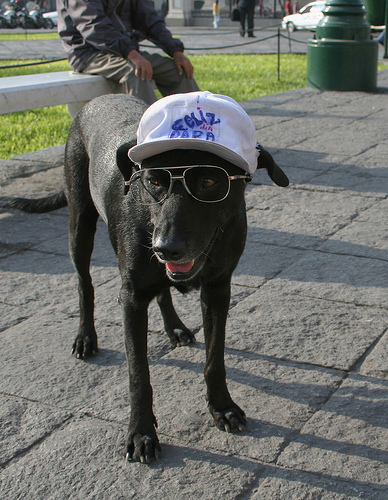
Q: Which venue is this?
A: This is a sidewalk.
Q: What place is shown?
A: It is a sidewalk.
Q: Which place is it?
A: It is a sidewalk.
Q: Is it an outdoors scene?
A: Yes, it is outdoors.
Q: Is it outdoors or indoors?
A: It is outdoors.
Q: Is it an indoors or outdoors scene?
A: It is outdoors.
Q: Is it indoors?
A: No, it is outdoors.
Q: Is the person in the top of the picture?
A: Yes, the person is in the top of the image.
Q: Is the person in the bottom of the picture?
A: No, the person is in the top of the image.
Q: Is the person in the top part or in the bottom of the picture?
A: The person is in the top of the image.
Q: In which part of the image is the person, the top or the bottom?
A: The person is in the top of the image.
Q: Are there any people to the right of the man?
A: Yes, there is a person to the right of the man.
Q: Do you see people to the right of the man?
A: Yes, there is a person to the right of the man.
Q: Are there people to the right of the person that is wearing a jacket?
A: Yes, there is a person to the right of the man.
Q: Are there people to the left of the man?
A: No, the person is to the right of the man.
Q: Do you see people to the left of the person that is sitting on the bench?
A: No, the person is to the right of the man.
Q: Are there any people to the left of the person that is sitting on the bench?
A: No, the person is to the right of the man.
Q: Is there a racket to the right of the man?
A: No, there is a person to the right of the man.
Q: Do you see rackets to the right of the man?
A: No, there is a person to the right of the man.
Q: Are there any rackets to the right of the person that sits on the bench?
A: No, there is a person to the right of the man.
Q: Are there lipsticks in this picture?
A: No, there are no lipsticks.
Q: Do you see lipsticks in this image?
A: No, there are no lipsticks.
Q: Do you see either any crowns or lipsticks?
A: No, there are no lipsticks or crowns.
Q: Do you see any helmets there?
A: No, there are no helmets.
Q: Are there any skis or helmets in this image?
A: No, there are no helmets or skis.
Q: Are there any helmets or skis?
A: No, there are no helmets or skis.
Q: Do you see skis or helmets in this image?
A: No, there are no helmets or skis.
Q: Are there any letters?
A: Yes, there are letters.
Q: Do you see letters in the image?
A: Yes, there are letters.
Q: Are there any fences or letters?
A: Yes, there are letters.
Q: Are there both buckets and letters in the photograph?
A: No, there are letters but no buckets.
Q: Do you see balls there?
A: No, there are no balls.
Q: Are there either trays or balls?
A: No, there are no balls or trays.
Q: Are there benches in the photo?
A: Yes, there is a bench.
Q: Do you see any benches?
A: Yes, there is a bench.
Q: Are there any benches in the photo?
A: Yes, there is a bench.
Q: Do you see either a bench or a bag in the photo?
A: Yes, there is a bench.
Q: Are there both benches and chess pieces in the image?
A: No, there is a bench but no chess pieces.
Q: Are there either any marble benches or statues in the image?
A: Yes, there is a marble bench.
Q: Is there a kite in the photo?
A: No, there are no kites.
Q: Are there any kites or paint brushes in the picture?
A: No, there are no kites or paint brushes.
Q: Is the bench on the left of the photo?
A: Yes, the bench is on the left of the image.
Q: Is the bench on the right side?
A: No, the bench is on the left of the image.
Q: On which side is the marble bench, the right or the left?
A: The bench is on the left of the image.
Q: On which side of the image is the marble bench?
A: The bench is on the left of the image.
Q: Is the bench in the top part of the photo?
A: Yes, the bench is in the top of the image.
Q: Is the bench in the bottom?
A: No, the bench is in the top of the image.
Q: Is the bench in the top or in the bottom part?
A: The bench is in the top of the image.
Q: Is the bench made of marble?
A: Yes, the bench is made of marble.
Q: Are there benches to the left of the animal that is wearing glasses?
A: Yes, there is a bench to the left of the dog.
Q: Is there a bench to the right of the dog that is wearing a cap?
A: No, the bench is to the left of the dog.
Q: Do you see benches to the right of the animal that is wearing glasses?
A: No, the bench is to the left of the dog.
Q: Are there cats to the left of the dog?
A: No, there is a bench to the left of the dog.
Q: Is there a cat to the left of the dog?
A: No, there is a bench to the left of the dog.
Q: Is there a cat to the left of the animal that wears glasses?
A: No, there is a bench to the left of the dog.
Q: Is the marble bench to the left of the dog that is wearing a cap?
A: Yes, the bench is to the left of the dog.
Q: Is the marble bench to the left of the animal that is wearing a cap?
A: Yes, the bench is to the left of the dog.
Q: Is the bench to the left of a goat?
A: No, the bench is to the left of the dog.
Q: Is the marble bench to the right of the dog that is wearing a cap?
A: No, the bench is to the left of the dog.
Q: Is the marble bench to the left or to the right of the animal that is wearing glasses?
A: The bench is to the left of the dog.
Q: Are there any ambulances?
A: No, there are no ambulances.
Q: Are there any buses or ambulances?
A: No, there are no ambulances or buses.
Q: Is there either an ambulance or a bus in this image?
A: No, there are no ambulances or buses.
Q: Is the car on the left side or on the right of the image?
A: The car is on the right of the image.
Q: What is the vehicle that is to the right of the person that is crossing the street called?
A: The vehicle is a car.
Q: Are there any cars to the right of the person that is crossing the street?
A: Yes, there is a car to the right of the person.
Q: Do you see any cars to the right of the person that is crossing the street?
A: Yes, there is a car to the right of the person.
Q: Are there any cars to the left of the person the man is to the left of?
A: No, the car is to the right of the person.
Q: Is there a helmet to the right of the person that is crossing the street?
A: No, there is a car to the right of the person.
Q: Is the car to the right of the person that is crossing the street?
A: Yes, the car is to the right of the person.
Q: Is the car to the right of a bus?
A: No, the car is to the right of the person.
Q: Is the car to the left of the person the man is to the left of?
A: No, the car is to the right of the person.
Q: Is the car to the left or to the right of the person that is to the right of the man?
A: The car is to the right of the person.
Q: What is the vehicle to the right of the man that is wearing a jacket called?
A: The vehicle is a car.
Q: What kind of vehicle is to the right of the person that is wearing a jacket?
A: The vehicle is a car.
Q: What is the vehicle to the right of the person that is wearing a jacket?
A: The vehicle is a car.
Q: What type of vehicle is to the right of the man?
A: The vehicle is a car.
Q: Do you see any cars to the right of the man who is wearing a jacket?
A: Yes, there is a car to the right of the man.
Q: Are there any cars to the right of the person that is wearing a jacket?
A: Yes, there is a car to the right of the man.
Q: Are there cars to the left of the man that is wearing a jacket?
A: No, the car is to the right of the man.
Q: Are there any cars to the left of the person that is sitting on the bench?
A: No, the car is to the right of the man.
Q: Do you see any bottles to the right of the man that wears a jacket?
A: No, there is a car to the right of the man.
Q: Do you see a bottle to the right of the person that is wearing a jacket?
A: No, there is a car to the right of the man.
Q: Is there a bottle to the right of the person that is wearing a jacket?
A: No, there is a car to the right of the man.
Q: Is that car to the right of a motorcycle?
A: No, the car is to the right of a man.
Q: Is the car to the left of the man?
A: No, the car is to the right of the man.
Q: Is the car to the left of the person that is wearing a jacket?
A: No, the car is to the right of the man.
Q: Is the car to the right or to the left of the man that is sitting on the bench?
A: The car is to the right of the man.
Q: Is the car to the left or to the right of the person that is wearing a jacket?
A: The car is to the right of the man.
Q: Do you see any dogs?
A: Yes, there is a dog.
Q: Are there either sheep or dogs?
A: Yes, there is a dog.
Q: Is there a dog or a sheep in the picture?
A: Yes, there is a dog.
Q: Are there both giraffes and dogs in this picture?
A: No, there is a dog but no giraffes.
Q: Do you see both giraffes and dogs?
A: No, there is a dog but no giraffes.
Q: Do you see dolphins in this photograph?
A: No, there are no dolphins.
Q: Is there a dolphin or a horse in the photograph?
A: No, there are no dolphins or horses.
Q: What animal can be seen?
A: The animal is a dog.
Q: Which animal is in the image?
A: The animal is a dog.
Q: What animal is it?
A: The animal is a dog.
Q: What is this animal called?
A: This is a dog.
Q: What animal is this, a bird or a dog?
A: This is a dog.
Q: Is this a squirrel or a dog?
A: This is a dog.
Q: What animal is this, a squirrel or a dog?
A: This is a dog.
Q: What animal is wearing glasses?
A: The dog is wearing glasses.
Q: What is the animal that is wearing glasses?
A: The animal is a dog.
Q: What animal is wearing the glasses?
A: The animal is a dog.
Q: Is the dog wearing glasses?
A: Yes, the dog is wearing glasses.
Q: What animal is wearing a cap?
A: The dog is wearing a cap.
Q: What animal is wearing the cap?
A: The dog is wearing a cap.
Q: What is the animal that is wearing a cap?
A: The animal is a dog.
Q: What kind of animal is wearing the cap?
A: The animal is a dog.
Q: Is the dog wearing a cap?
A: Yes, the dog is wearing a cap.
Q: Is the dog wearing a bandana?
A: No, the dog is wearing a cap.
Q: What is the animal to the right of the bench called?
A: The animal is a dog.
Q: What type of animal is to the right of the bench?
A: The animal is a dog.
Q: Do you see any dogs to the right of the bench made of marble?
A: Yes, there is a dog to the right of the bench.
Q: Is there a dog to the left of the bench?
A: No, the dog is to the right of the bench.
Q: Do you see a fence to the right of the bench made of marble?
A: No, there is a dog to the right of the bench.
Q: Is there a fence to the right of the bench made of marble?
A: No, there is a dog to the right of the bench.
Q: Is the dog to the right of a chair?
A: No, the dog is to the right of the bench.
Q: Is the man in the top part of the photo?
A: Yes, the man is in the top of the image.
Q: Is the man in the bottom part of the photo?
A: No, the man is in the top of the image.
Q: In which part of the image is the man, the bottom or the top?
A: The man is in the top of the image.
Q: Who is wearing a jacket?
A: The man is wearing a jacket.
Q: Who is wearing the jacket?
A: The man is wearing a jacket.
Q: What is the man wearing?
A: The man is wearing a jacket.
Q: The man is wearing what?
A: The man is wearing a jacket.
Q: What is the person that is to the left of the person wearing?
A: The man is wearing a jacket.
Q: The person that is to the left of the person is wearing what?
A: The man is wearing a jacket.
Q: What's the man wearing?
A: The man is wearing a jacket.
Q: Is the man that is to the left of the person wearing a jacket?
A: Yes, the man is wearing a jacket.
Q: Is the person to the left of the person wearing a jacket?
A: Yes, the man is wearing a jacket.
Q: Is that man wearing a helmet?
A: No, the man is wearing a jacket.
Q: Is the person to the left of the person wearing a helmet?
A: No, the man is wearing a jacket.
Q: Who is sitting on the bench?
A: The man is sitting on the bench.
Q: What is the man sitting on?
A: The man is sitting on the bench.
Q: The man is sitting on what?
A: The man is sitting on the bench.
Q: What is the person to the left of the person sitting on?
A: The man is sitting on the bench.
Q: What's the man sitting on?
A: The man is sitting on the bench.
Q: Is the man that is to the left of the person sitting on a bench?
A: Yes, the man is sitting on a bench.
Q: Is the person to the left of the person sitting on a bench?
A: Yes, the man is sitting on a bench.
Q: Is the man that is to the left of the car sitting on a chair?
A: No, the man is sitting on a bench.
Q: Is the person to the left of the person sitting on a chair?
A: No, the man is sitting on a bench.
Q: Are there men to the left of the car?
A: Yes, there is a man to the left of the car.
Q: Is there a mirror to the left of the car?
A: No, there is a man to the left of the car.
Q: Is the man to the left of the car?
A: Yes, the man is to the left of the car.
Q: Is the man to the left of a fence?
A: No, the man is to the left of the car.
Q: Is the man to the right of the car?
A: No, the man is to the left of the car.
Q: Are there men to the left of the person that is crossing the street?
A: Yes, there is a man to the left of the person.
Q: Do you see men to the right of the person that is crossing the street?
A: No, the man is to the left of the person.